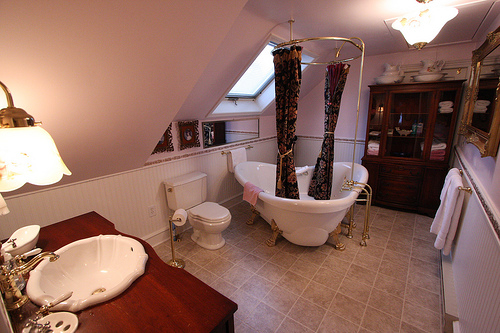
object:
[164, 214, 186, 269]
dispenser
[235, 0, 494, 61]
roof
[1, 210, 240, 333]
table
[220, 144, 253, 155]
holder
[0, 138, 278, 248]
wall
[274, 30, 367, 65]
ring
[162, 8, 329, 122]
roof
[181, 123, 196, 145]
pictures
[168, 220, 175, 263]
holder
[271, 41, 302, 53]
tassel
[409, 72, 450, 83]
bowl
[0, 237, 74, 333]
faucet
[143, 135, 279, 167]
ledge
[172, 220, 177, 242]
stand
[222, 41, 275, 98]
window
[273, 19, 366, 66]
rod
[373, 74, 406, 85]
basins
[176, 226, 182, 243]
stand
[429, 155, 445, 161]
towels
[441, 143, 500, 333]
wall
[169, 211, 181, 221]
holder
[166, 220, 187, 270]
stand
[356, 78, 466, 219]
cabinet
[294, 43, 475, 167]
wall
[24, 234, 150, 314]
sink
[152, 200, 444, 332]
floor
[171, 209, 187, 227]
paper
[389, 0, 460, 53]
light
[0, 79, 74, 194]
lamp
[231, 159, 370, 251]
bathtub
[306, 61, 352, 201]
curtain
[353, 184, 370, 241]
pipe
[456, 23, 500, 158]
mirror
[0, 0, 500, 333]
bathroom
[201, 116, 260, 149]
frames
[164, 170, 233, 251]
toilet